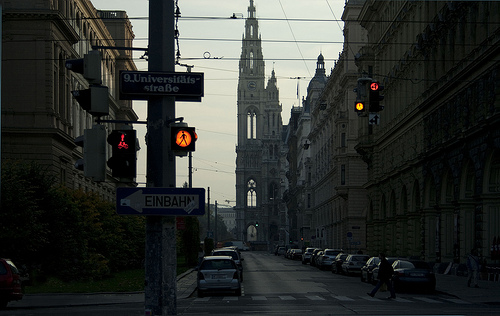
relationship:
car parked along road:
[389, 259, 419, 280] [242, 244, 385, 311]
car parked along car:
[359, 256, 385, 275] [389, 259, 419, 280]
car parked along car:
[338, 250, 370, 277] [389, 259, 419, 280]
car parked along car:
[321, 243, 348, 272] [389, 259, 419, 280]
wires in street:
[63, 0, 417, 174] [0, 0, 483, 313]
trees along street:
[8, 167, 82, 294] [1, 250, 471, 314]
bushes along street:
[68, 186, 148, 276] [1, 250, 471, 314]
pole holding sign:
[143, 0, 179, 315] [110, 68, 206, 95]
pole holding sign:
[143, 0, 179, 315] [115, 64, 211, 110]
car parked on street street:
[359, 254, 381, 277] [173, 228, 428, 311]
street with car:
[190, 246, 450, 314] [195, 254, 245, 290]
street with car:
[190, 246, 450, 314] [389, 259, 419, 280]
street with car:
[190, 246, 450, 314] [338, 250, 370, 277]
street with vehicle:
[190, 246, 450, 314] [320, 247, 340, 266]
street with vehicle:
[190, 246, 450, 314] [303, 246, 313, 261]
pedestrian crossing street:
[365, 249, 405, 313] [174, 214, 419, 304]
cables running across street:
[6, 7, 490, 74] [152, 202, 446, 312]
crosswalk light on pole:
[174, 129, 192, 149] [133, 32, 180, 302]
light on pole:
[103, 127, 136, 151] [133, 32, 180, 302]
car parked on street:
[376, 253, 425, 290] [192, 245, 499, 314]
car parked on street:
[359, 251, 386, 275] [192, 245, 499, 314]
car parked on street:
[334, 250, 364, 270] [192, 245, 499, 314]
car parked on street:
[195, 250, 245, 290] [192, 245, 499, 314]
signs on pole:
[117, 180, 202, 216] [138, 24, 191, 294]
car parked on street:
[195, 254, 245, 290] [24, 238, 487, 313]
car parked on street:
[389, 259, 419, 280] [24, 238, 487, 313]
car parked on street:
[338, 250, 370, 277] [24, 238, 487, 313]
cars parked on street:
[301, 244, 324, 264] [24, 238, 487, 313]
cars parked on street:
[281, 243, 305, 260] [24, 238, 487, 313]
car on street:
[338, 250, 370, 277] [187, 237, 477, 314]